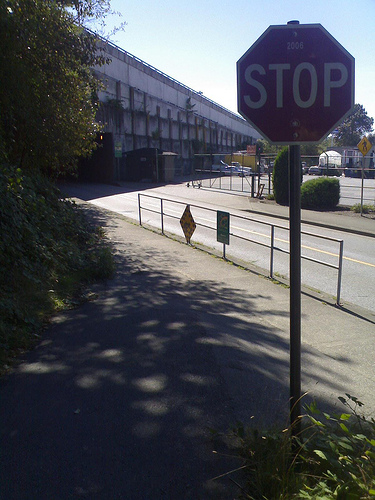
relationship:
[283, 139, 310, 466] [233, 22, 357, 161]
pole supporting sign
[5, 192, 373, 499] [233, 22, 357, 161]
concrete near sign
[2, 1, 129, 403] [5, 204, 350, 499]
trees have shadow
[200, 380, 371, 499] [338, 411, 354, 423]
plant has leaves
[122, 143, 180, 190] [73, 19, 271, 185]
dumpster outside of bridge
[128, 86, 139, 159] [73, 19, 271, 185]
pipes running down bridge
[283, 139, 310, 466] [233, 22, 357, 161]
pole has sign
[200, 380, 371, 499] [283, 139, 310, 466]
plant are down on pole